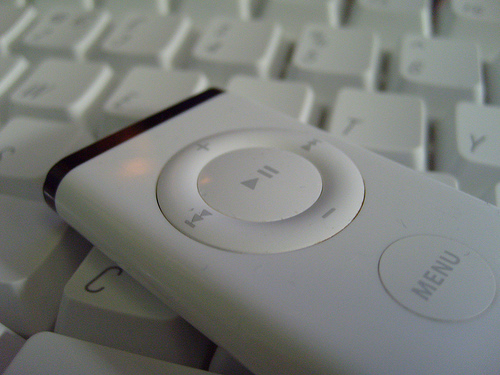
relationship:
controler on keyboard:
[41, 83, 499, 373] [0, 1, 496, 373]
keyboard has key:
[0, 1, 496, 373] [322, 84, 432, 166]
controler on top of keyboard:
[41, 83, 499, 373] [0, 1, 496, 373]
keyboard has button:
[0, 1, 496, 373] [49, 237, 209, 366]